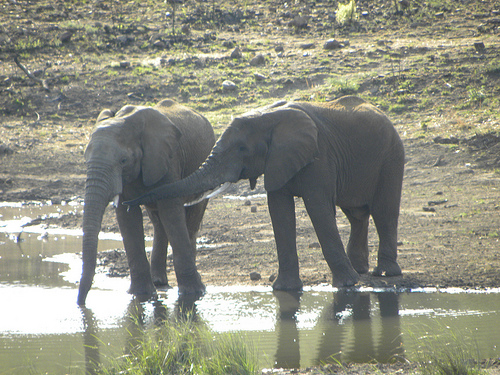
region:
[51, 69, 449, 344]
two elephants near a body of water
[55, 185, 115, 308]
the trunk of an elephant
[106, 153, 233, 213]
the trunk of an elephant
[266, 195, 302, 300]
the leg of an elephant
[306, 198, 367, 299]
the leg of an elephant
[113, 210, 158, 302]
the leg of an elephant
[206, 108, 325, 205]
the head of an elephant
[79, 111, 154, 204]
the head of an elephant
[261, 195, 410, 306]
the legs of an elephant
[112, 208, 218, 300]
the legs of an elephant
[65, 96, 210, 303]
The short tusked jumbo on the left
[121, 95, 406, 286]
The patting elephant on the right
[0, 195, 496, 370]
The water logged space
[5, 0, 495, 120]
The sparsely growing grass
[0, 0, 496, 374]
Two elephants in the wild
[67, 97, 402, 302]
The gray tusked elephants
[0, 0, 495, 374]
The sloping hill in the wild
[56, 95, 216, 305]
The drinking elephant on the left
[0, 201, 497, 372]
A marshy drinking area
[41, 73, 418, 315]
two elephants by the watering hole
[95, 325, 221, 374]
green grass growing by the water hole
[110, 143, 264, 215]
elephant is reaching trunk out to the other elephant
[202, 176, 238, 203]
white ivory tusks on the elephant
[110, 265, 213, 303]
elephant's feet are in the water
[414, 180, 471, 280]
dirt behind the watering hole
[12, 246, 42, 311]
water in the watering hole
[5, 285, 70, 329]
light reflecting on the water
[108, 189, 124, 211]
ivory tusk is very short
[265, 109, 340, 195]
large elephant ear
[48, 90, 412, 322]
two elephants in water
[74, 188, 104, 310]
elephant trunk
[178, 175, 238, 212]
two elephant tusk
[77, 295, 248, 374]
tall green grass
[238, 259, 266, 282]
rock in grass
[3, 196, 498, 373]
water hole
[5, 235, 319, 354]
white light reflected on surface of water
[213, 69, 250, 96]
rock on grass covered hill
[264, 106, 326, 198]
grey elephant ear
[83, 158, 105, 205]
wrinkles on elephant trunk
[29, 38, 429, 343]
Two elephants standing near the edge of the water.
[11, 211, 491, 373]
Water running through a field.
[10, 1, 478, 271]
Rocky landscape behind the elephants.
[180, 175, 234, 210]
Tusks on the elephant on the right.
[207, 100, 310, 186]
Head of the elephant on the right.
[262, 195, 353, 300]
Front legs of the elephant on the right.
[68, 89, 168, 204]
Head of the elephant on the left.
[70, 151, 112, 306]
Trunk of the elephant on the left.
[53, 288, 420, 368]
Reflection of the elephants in the water.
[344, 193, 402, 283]
Back legs of the elephant on the right.